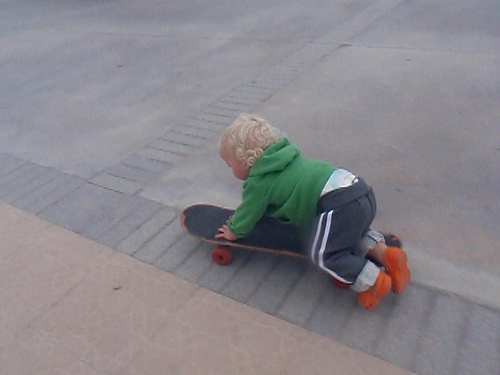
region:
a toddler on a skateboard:
[178, 113, 413, 311]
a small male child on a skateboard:
[177, 114, 412, 311]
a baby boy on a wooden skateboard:
[178, 113, 411, 313]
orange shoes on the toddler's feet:
[355, 245, 412, 310]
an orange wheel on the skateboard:
[211, 245, 231, 267]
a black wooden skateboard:
[180, 200, 402, 261]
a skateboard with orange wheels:
[181, 203, 402, 288]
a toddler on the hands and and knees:
[180, 114, 412, 310]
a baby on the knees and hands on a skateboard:
[181, 112, 412, 311]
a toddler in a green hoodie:
[214, 109, 413, 309]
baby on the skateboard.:
[204, 112, 414, 310]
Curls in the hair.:
[230, 139, 265, 169]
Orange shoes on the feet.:
[355, 246, 415, 313]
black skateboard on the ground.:
[172, 192, 404, 272]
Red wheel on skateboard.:
[207, 242, 237, 267]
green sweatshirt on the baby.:
[191, 105, 332, 245]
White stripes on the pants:
[306, 206, 353, 291]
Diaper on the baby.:
[314, 165, 361, 199]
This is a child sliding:
[171, 112, 441, 339]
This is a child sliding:
[173, 111, 427, 328]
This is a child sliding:
[175, 109, 431, 325]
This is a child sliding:
[179, 114, 431, 324]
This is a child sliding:
[176, 112, 413, 317]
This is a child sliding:
[178, 111, 413, 321]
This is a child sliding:
[174, 109, 418, 322]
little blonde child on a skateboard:
[215, 113, 412, 313]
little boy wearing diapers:
[214, 114, 412, 306]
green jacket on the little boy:
[226, 144, 332, 238]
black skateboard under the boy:
[182, 204, 348, 285]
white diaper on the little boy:
[319, 169, 356, 200]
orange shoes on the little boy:
[356, 250, 409, 312]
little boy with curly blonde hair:
[217, 116, 410, 311]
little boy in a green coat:
[217, 115, 412, 307]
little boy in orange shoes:
[220, 113, 410, 312]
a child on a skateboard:
[188, 101, 385, 363]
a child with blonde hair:
[211, 89, 346, 240]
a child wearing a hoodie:
[222, 110, 279, 276]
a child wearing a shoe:
[370, 261, 420, 358]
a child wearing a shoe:
[379, 235, 426, 319]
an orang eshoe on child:
[365, 268, 393, 324]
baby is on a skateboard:
[181, 117, 411, 310]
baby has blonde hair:
[213, 116, 272, 181]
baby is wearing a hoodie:
[211, 117, 326, 245]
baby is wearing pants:
[310, 185, 379, 290]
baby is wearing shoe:
[354, 279, 392, 315]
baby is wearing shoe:
[385, 247, 409, 295]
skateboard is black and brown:
[180, 201, 410, 266]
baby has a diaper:
[317, 167, 358, 198]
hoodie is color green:
[222, 141, 328, 233]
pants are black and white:
[311, 180, 381, 296]